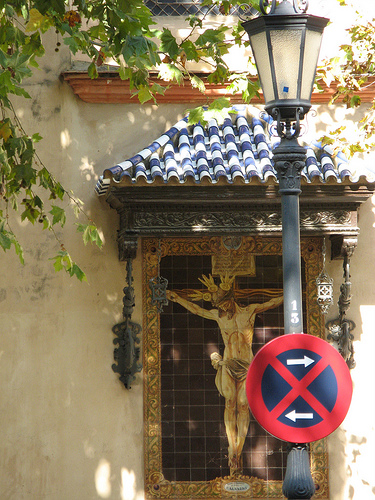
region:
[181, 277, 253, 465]
a statue on a building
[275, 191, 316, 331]
a pole of a lamp stand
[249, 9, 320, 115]
a lamp on a stand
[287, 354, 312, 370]
a white arrow pointing to the right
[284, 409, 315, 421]
a white arrow pointing to the left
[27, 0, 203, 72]
leaves hanging near the building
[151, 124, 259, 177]
colored tiles on a building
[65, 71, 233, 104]
the fresher board of a building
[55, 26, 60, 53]
fruits hanging from a branch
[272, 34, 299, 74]
a glass on the lamp stand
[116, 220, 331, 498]
A painting of a crucifix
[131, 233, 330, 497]
A painting of Jesus on a cross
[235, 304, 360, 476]
A red, white and blue street sign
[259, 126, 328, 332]
A gray metal lamp pole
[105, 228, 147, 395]
A gray metal window fixture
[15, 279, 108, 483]
A white building wall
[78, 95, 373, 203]
A blue and white tiled awning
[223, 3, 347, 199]
A decorative metal street lamp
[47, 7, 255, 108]
Green grape leaves and vines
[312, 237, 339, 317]
A decorative metal fixture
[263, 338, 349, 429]
the sign is circular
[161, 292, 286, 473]
jesuus is on the wall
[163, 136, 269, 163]
the roof is grey and white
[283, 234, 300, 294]
the light post is grey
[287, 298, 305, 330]
number 13 is on the light post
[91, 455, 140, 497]
light spots are on the walll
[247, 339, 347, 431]
a cross sign is on the sign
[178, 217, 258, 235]
the frame is mettalic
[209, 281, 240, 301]
crown of thorns is on the head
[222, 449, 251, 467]
nail is on the leg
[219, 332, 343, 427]
a sign on the lamp pole.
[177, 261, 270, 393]
Jesus on the cross.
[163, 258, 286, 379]
A sculpture of Jesus on the building.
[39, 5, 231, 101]
Trees hanging off the roof of building.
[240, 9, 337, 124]
Street light on the pole.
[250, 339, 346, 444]
The sign has two arrows.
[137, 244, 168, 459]
The trimming is gole.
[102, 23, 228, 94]
Leaves on the branch.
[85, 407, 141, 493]
A reflection of light on the wall.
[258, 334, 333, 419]
The sign is red and blue.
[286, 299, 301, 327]
numbers on the pole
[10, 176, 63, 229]
the leaves are green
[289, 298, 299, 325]
the numbers are white on the pole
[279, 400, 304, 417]
the arrows are white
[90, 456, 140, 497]
the light on the building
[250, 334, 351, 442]
a sign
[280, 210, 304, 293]
the pole is grey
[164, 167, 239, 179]
the roof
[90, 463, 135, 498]
the sunlight on the wall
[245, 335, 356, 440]
the sign is red and blue